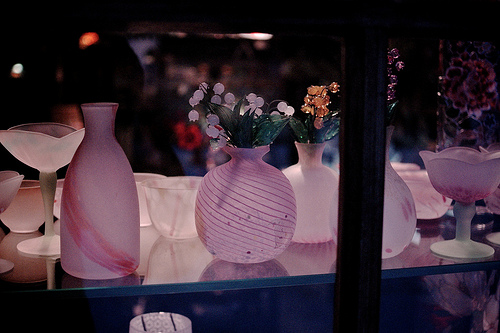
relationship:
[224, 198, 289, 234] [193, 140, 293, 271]
pattern on vase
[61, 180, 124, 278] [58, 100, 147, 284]
color on vase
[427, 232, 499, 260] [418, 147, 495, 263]
base on vase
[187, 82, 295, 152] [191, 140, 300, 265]
flowers in vase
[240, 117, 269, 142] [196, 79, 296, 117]
leaves on flowers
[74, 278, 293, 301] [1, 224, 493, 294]
edge on top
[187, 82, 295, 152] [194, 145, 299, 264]
flowers are in vase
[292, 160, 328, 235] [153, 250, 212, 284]
vase on counter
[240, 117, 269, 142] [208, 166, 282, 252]
leaves are in vase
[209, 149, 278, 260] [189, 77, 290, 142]
vase has little white flowers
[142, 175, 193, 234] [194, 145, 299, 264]
cup behind vase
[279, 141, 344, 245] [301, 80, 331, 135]
vase has little orange flowers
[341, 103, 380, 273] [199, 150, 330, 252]
pole in front of vases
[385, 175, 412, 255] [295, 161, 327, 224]
vase hidden by vase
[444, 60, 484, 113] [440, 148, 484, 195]
flower behind glass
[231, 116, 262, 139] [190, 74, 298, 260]
stems are on plants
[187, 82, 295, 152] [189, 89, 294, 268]
flowers are on plants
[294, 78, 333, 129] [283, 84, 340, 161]
flowers are on plants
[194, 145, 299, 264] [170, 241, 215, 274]
vase are on surface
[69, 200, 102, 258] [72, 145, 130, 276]
stripe on a vase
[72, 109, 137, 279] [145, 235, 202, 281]
vase on a table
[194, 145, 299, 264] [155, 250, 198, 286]
vase on a table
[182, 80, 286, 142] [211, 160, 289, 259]
flowers in a vase